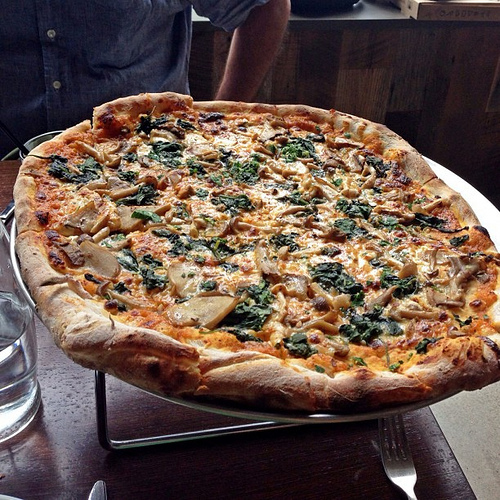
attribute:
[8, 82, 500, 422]
pizza — uncut, large, lifted up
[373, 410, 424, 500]
fork — silver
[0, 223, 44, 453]
container — clear, glass, round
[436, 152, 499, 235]
tray — wood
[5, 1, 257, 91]
shirt — blue, brown denim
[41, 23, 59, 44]
button — white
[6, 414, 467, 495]
table — dark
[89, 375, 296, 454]
stand — metal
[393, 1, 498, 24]
box — cardboard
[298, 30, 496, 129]
wall — wood